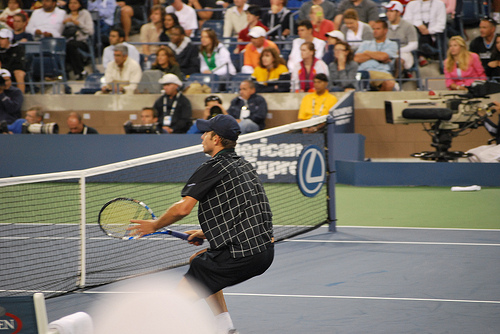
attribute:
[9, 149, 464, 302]
tennis court — blue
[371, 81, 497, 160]
camera — large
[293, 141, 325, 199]
lexus symbol — white, blue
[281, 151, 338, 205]
symbol — blue, white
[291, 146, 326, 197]
lexus symbol — blue, white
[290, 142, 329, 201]
symbol — blue, white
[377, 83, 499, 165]
camera — tan, blac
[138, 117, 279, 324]
man — white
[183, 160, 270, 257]
shirt — black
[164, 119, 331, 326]
person — playing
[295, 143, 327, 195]
design — white, blue, circular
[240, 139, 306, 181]
print — white, bold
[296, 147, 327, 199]
symbol — white, blue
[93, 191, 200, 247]
racket — white, blue, black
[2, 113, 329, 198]
trim — white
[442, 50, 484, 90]
blazer — pink